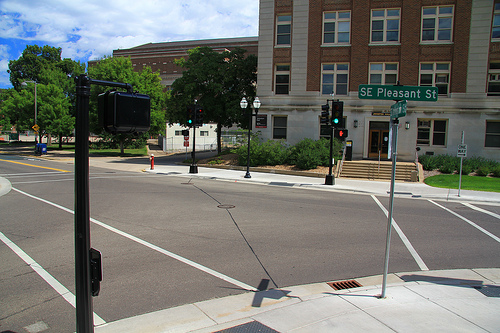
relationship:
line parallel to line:
[1, 229, 107, 325] [10, 183, 259, 294]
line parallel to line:
[370, 191, 429, 273] [424, 195, 499, 252]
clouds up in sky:
[0, 0, 259, 90] [1, 2, 260, 90]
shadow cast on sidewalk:
[397, 271, 499, 297] [192, 275, 498, 331]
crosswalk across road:
[1, 183, 257, 323] [1, 151, 498, 333]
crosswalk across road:
[373, 189, 499, 276] [1, 151, 498, 333]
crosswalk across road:
[11, 166, 168, 183] [1, 151, 498, 333]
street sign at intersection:
[353, 83, 438, 103] [13, 170, 422, 288]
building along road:
[247, 0, 498, 173] [1, 151, 498, 333]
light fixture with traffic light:
[329, 97, 345, 127] [332, 117, 340, 127]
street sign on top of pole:
[353, 83, 438, 103] [375, 120, 399, 299]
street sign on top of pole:
[384, 98, 408, 122] [375, 120, 399, 299]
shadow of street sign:
[226, 275, 377, 308] [353, 83, 438, 103]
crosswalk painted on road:
[1, 183, 257, 323] [1, 151, 498, 333]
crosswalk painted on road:
[373, 189, 499, 276] [1, 151, 498, 333]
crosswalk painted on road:
[11, 166, 168, 183] [1, 151, 498, 333]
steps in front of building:
[335, 155, 423, 185] [247, 0, 498, 173]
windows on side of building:
[319, 4, 457, 49] [247, 0, 498, 173]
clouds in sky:
[0, 0, 259, 90] [1, 2, 260, 90]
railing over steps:
[335, 141, 348, 177] [335, 155, 423, 185]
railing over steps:
[374, 145, 383, 178] [335, 155, 423, 185]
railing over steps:
[412, 149, 420, 181] [335, 155, 423, 185]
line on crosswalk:
[1, 229, 107, 325] [1, 183, 257, 323]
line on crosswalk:
[10, 183, 259, 294] [1, 183, 257, 323]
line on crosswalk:
[370, 191, 429, 273] [373, 189, 499, 276]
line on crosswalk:
[424, 195, 499, 252] [373, 189, 499, 276]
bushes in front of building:
[235, 131, 343, 171] [247, 0, 498, 173]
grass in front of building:
[422, 170, 498, 193] [247, 0, 498, 173]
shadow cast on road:
[226, 275, 377, 308] [1, 151, 498, 333]